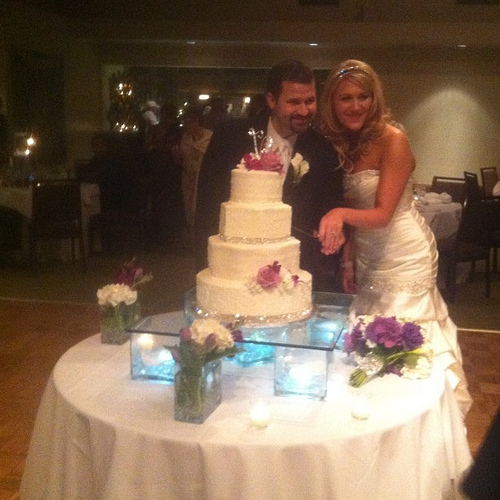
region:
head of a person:
[327, 56, 384, 141]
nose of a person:
[345, 101, 375, 121]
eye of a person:
[324, 88, 362, 112]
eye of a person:
[354, 85, 371, 109]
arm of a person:
[355, 149, 425, 251]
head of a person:
[238, 53, 346, 133]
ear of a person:
[252, 89, 287, 111]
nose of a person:
[292, 106, 310, 120]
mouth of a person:
[288, 113, 318, 127]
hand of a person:
[314, 211, 345, 242]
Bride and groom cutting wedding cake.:
[190, 45, 469, 322]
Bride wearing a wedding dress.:
[340, 167, 472, 425]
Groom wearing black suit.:
[192, 108, 337, 265]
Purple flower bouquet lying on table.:
[342, 314, 429, 394]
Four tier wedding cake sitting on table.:
[184, 147, 321, 327]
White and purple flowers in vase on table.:
[93, 256, 150, 353]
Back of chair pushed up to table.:
[23, 174, 94, 276]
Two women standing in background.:
[138, 99, 210, 247]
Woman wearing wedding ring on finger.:
[326, 227, 340, 242]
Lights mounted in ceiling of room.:
[182, 32, 480, 57]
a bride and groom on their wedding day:
[192, 52, 451, 309]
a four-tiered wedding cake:
[190, 119, 318, 322]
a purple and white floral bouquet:
[342, 308, 437, 389]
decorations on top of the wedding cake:
[234, 121, 287, 170]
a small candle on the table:
[248, 396, 273, 429]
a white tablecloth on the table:
[18, 303, 475, 497]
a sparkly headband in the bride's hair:
[335, 65, 372, 77]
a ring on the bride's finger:
[328, 229, 335, 236]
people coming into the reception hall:
[141, 91, 219, 233]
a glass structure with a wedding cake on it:
[123, 275, 358, 401]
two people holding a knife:
[188, 43, 443, 347]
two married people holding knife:
[215, 60, 422, 307]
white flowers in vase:
[175, 323, 233, 360]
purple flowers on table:
[357, 308, 438, 365]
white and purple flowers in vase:
[98, 252, 151, 318]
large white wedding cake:
[192, 154, 309, 337]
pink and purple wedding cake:
[235, 146, 287, 176]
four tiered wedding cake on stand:
[173, 137, 325, 348]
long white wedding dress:
[323, 161, 438, 336]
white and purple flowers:
[173, 308, 260, 371]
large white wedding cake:
[188, 143, 305, 323]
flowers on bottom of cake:
[238, 263, 310, 305]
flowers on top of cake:
[240, 150, 273, 175]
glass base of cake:
[263, 313, 351, 359]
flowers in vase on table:
[168, 310, 230, 422]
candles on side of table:
[333, 385, 385, 440]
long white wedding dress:
[310, 154, 463, 323]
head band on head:
[329, 62, 386, 94]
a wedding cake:
[188, 156, 323, 328]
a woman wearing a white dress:
[317, 53, 475, 440]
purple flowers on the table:
[340, 317, 423, 382]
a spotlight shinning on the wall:
[390, 74, 493, 188]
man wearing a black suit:
[187, 56, 352, 296]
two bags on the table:
[89, 260, 239, 426]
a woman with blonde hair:
[309, 53, 474, 428]